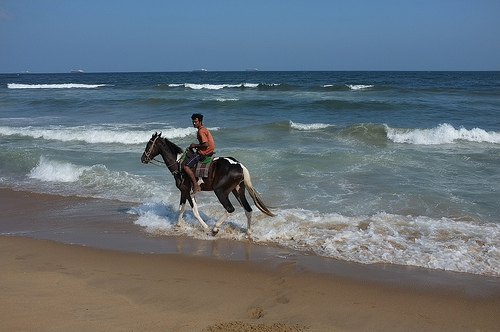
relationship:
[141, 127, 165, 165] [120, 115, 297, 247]
face on horse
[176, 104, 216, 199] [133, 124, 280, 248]
boy on horse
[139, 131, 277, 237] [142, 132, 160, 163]
black horse wearing bridle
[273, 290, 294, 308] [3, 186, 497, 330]
footprint in sand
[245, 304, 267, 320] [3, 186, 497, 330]
footprint in sand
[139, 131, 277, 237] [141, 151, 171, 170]
black horse wearing reins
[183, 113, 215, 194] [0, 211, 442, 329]
boy no wears beach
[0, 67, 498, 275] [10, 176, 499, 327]
water washing onto shore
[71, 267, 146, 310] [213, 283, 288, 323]
sand on beach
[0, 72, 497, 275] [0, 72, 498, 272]
water in ocean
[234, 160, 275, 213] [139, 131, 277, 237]
tail of black horse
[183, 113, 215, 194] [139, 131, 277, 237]
boy riding black horse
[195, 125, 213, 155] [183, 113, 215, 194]
orange shirt on boy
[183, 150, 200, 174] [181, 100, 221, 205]
black shorts on man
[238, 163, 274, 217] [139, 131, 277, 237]
tail on black horse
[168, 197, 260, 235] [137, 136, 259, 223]
legs on horse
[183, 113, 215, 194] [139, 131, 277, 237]
boy on black horse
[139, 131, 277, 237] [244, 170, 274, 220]
black horse with tail